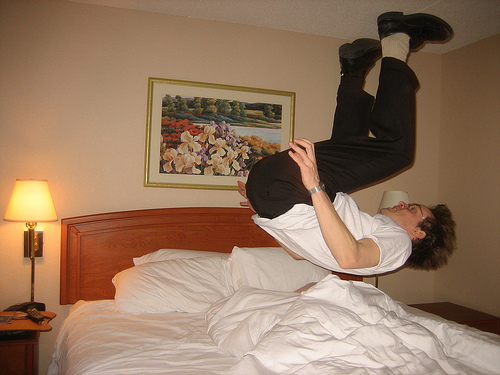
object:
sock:
[378, 34, 416, 62]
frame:
[141, 76, 300, 193]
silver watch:
[302, 179, 327, 198]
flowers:
[177, 141, 219, 163]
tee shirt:
[247, 190, 411, 275]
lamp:
[0, 171, 61, 327]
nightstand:
[0, 299, 56, 375]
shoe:
[374, 8, 456, 48]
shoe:
[335, 36, 382, 74]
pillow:
[108, 258, 229, 318]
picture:
[147, 71, 302, 195]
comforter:
[53, 246, 499, 371]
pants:
[246, 57, 422, 216]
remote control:
[25, 305, 44, 322]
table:
[1, 311, 56, 373]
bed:
[54, 207, 498, 374]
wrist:
[307, 170, 345, 214]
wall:
[0, 0, 499, 375]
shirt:
[245, 199, 420, 277]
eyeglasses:
[402, 195, 428, 226]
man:
[241, 8, 462, 275]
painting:
[158, 93, 284, 182]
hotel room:
[0, 0, 499, 375]